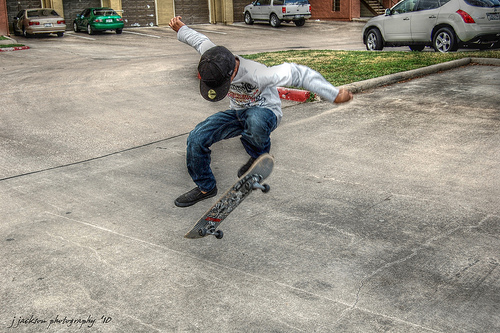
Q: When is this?
A: Daytime.